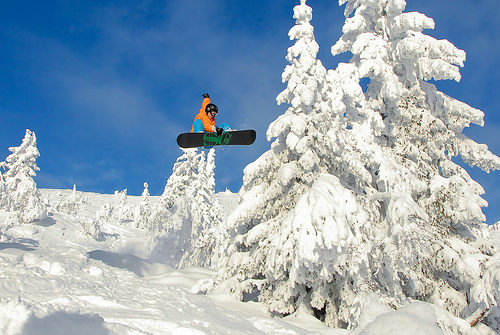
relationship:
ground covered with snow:
[1, 192, 491, 333] [1, 194, 496, 333]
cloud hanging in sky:
[68, 83, 149, 136] [48, 38, 206, 147]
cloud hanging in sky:
[64, 154, 94, 170] [48, 38, 206, 147]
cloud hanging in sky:
[95, 157, 107, 166] [48, 38, 206, 147]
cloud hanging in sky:
[92, 20, 176, 80] [48, 38, 206, 147]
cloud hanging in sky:
[312, 11, 346, 62] [48, 38, 206, 147]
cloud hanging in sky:
[69, 160, 88, 173] [4, 0, 498, 218]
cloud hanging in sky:
[95, 157, 109, 165] [4, 0, 498, 218]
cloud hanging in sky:
[52, 75, 152, 145] [4, 0, 498, 218]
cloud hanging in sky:
[60, 20, 81, 38] [4, 0, 498, 218]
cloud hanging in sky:
[310, 3, 344, 61] [4, 0, 498, 218]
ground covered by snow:
[1, 192, 491, 333] [1, 194, 496, 333]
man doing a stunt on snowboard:
[190, 89, 231, 136] [145, 119, 310, 159]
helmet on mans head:
[204, 101, 219, 116] [204, 98, 219, 118]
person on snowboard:
[172, 91, 260, 150] [177, 127, 258, 150]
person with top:
[172, 91, 260, 150] [193, 95, 220, 127]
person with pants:
[172, 91, 260, 150] [184, 119, 233, 132]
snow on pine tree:
[275, 41, 420, 266] [221, 4, 426, 319]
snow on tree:
[13, 250, 165, 326] [337, 2, 494, 327]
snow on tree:
[13, 250, 165, 326] [219, 3, 348, 316]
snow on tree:
[13, 250, 165, 326] [155, 151, 224, 267]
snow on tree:
[13, 250, 165, 326] [133, 176, 155, 233]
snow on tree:
[13, 250, 165, 326] [8, 128, 46, 224]